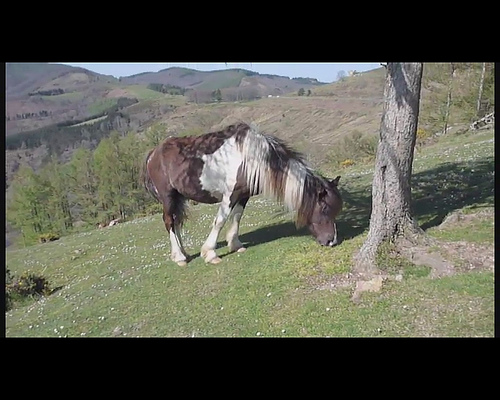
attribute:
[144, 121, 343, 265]
horse — white, brown, standing, grazing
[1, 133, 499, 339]
grass — green, short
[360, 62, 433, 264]
trunk — gray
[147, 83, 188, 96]
trees — cluster, green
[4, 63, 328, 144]
hills — rolling, brown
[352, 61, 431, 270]
tree — brown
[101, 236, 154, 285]
flowers — white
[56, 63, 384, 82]
sky — blue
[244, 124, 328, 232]
mane — long, striped, white, thin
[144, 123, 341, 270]
pony — white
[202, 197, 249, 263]
legs — white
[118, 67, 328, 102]
mountains — distant